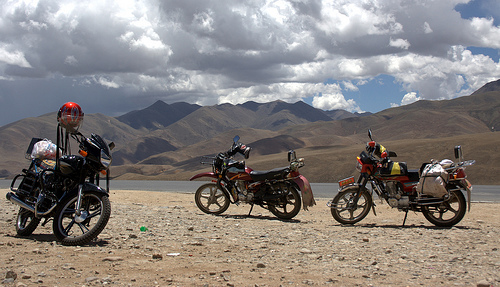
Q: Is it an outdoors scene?
A: Yes, it is outdoors.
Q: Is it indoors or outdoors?
A: It is outdoors.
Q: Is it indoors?
A: No, it is outdoors.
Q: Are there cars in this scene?
A: No, there are no cars.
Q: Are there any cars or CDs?
A: No, there are no cars or cds.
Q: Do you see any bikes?
A: Yes, there is a bike.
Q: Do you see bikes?
A: Yes, there is a bike.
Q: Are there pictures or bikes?
A: Yes, there is a bike.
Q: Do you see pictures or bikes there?
A: Yes, there is a bike.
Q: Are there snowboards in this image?
A: No, there are no snowboards.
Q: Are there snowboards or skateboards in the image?
A: No, there are no snowboards or skateboards.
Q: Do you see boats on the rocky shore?
A: No, there is a bike on the sea shore.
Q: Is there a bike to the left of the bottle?
A: Yes, there is a bike to the left of the bottle.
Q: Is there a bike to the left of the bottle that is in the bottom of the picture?
A: Yes, there is a bike to the left of the bottle.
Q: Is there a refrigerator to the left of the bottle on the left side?
A: No, there is a bike to the left of the bottle.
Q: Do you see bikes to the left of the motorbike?
A: Yes, there is a bike to the left of the motorbike.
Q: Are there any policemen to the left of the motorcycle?
A: No, there is a bike to the left of the motorcycle.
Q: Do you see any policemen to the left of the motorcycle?
A: No, there is a bike to the left of the motorcycle.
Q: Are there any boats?
A: No, there are no boats.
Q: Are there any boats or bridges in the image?
A: No, there are no boats or bridges.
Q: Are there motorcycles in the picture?
A: Yes, there is a motorcycle.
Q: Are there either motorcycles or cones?
A: Yes, there is a motorcycle.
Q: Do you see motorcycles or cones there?
A: Yes, there is a motorcycle.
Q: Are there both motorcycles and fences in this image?
A: No, there is a motorcycle but no fences.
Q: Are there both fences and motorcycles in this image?
A: No, there is a motorcycle but no fences.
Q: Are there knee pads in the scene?
A: No, there are no knee pads.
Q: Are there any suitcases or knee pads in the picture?
A: No, there are no knee pads or suitcases.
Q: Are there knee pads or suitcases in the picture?
A: No, there are no knee pads or suitcases.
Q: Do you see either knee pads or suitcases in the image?
A: No, there are no knee pads or suitcases.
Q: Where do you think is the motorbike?
A: The motorbike is on the sea shore.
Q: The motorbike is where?
A: The motorbike is on the sea shore.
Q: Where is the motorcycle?
A: The motorbike is on the sea shore.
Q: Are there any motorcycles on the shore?
A: Yes, there is a motorcycle on the shore.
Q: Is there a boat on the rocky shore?
A: No, there is a motorcycle on the shore.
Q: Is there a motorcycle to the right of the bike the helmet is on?
A: Yes, there is a motorcycle to the right of the bike.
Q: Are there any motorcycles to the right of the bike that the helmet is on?
A: Yes, there is a motorcycle to the right of the bike.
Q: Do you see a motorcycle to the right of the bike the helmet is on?
A: Yes, there is a motorcycle to the right of the bike.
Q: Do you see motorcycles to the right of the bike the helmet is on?
A: Yes, there is a motorcycle to the right of the bike.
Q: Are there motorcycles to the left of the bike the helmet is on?
A: No, the motorcycle is to the right of the bike.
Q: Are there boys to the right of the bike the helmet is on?
A: No, there is a motorcycle to the right of the bike.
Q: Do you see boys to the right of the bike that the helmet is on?
A: No, there is a motorcycle to the right of the bike.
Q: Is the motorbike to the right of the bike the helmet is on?
A: Yes, the motorbike is to the right of the bike.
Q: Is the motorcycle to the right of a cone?
A: No, the motorcycle is to the right of the bike.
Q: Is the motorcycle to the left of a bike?
A: No, the motorcycle is to the right of a bike.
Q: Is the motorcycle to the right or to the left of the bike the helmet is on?
A: The motorcycle is to the right of the bike.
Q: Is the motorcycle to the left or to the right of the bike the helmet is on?
A: The motorcycle is to the right of the bike.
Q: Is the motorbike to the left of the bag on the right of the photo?
A: Yes, the motorbike is to the left of the bag.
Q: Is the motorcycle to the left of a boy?
A: No, the motorcycle is to the left of the bag.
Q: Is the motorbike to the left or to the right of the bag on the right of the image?
A: The motorbike is to the left of the bag.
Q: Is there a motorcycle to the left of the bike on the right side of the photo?
A: Yes, there is a motorcycle to the left of the bike.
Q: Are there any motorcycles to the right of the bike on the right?
A: No, the motorcycle is to the left of the bike.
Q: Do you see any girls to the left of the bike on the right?
A: No, there is a motorcycle to the left of the bike.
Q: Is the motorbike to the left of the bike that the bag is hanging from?
A: Yes, the motorbike is to the left of the bike.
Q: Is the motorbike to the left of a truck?
A: No, the motorbike is to the left of the bike.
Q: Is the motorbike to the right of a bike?
A: No, the motorbike is to the left of a bike.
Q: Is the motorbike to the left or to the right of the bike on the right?
A: The motorbike is to the left of the bike.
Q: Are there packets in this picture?
A: No, there are no packets.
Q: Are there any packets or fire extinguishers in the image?
A: No, there are no packets or fire extinguishers.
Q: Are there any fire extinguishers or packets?
A: No, there are no packets or fire extinguishers.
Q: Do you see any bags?
A: Yes, there is a bag.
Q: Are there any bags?
A: Yes, there is a bag.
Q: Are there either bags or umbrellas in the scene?
A: Yes, there is a bag.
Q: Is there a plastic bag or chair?
A: Yes, there is a plastic bag.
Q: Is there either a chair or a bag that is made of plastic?
A: Yes, the bag is made of plastic.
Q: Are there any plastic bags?
A: Yes, there is a bag that is made of plastic.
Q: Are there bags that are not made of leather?
A: Yes, there is a bag that is made of plastic.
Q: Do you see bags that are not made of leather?
A: Yes, there is a bag that is made of plastic.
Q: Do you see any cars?
A: No, there are no cars.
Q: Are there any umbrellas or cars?
A: No, there are no cars or umbrellas.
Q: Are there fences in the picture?
A: No, there are no fences.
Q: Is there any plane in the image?
A: No, there are no airplanes.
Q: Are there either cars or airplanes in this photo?
A: No, there are no airplanes or cars.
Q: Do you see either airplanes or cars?
A: No, there are no airplanes or cars.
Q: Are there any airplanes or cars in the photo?
A: No, there are no airplanes or cars.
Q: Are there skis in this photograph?
A: No, there are no skis.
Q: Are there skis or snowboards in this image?
A: No, there are no skis or snowboards.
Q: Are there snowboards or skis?
A: No, there are no skis or snowboards.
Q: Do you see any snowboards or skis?
A: No, there are no skis or snowboards.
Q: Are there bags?
A: Yes, there is a bag.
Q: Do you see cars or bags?
A: Yes, there is a bag.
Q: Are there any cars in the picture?
A: No, there are no cars.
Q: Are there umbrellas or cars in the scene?
A: No, there are no cars or umbrellas.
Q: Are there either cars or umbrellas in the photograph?
A: No, there are no cars or umbrellas.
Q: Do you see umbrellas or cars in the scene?
A: No, there are no cars or umbrellas.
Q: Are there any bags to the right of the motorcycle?
A: Yes, there is a bag to the right of the motorcycle.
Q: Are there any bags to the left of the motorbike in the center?
A: No, the bag is to the right of the motorbike.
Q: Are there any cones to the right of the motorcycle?
A: No, there is a bag to the right of the motorcycle.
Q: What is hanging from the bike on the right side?
A: The bag is hanging from the bike.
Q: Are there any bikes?
A: Yes, there is a bike.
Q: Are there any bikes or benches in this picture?
A: Yes, there is a bike.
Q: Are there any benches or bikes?
A: Yes, there is a bike.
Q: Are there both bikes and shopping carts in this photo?
A: No, there is a bike but no shopping carts.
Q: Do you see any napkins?
A: No, there are no napkins.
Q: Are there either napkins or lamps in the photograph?
A: No, there are no napkins or lamps.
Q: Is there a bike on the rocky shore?
A: Yes, there is a bike on the sea shore.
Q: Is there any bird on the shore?
A: No, there is a bike on the shore.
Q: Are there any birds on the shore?
A: No, there is a bike on the shore.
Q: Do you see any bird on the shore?
A: No, there is a bike on the shore.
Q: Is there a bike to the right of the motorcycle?
A: Yes, there is a bike to the right of the motorcycle.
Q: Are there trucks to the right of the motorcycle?
A: No, there is a bike to the right of the motorcycle.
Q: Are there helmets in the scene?
A: Yes, there is a helmet.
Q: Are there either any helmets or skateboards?
A: Yes, there is a helmet.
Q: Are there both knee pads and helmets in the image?
A: No, there is a helmet but no knee pads.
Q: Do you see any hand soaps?
A: No, there are no hand soaps.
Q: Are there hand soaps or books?
A: No, there are no hand soaps or books.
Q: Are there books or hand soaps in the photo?
A: No, there are no hand soaps or books.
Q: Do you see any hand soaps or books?
A: No, there are no hand soaps or books.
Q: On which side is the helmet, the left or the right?
A: The helmet is on the left of the image.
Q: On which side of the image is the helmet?
A: The helmet is on the left of the image.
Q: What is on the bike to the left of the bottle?
A: The helmet is on the bike.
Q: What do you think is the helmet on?
A: The helmet is on the bike.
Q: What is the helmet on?
A: The helmet is on the bike.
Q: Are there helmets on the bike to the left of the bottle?
A: Yes, there is a helmet on the bike.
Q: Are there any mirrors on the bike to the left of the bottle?
A: No, there is a helmet on the bike.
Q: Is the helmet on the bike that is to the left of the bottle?
A: Yes, the helmet is on the bike.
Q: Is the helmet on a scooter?
A: No, the helmet is on the bike.